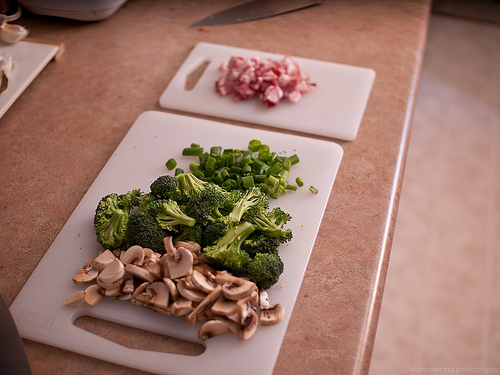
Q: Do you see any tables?
A: Yes, there is a table.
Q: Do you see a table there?
A: Yes, there is a table.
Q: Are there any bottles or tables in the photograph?
A: Yes, there is a table.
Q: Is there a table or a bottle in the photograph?
A: Yes, there is a table.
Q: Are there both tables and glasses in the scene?
A: No, there is a table but no glasses.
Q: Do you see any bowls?
A: No, there are no bowls.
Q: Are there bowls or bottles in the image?
A: No, there are no bowls or bottles.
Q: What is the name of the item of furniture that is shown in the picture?
A: The piece of furniture is a table.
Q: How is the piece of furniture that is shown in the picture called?
A: The piece of furniture is a table.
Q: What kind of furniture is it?
A: The piece of furniture is a table.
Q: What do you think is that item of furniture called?
A: This is a table.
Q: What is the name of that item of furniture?
A: This is a table.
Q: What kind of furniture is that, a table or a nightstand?
A: This is a table.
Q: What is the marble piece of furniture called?
A: The piece of furniture is a table.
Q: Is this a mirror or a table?
A: This is a table.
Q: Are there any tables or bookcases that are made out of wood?
A: No, there is a table but it is made of marble.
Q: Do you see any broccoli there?
A: Yes, there is broccoli.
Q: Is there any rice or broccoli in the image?
A: Yes, there is broccoli.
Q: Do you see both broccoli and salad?
A: No, there is broccoli but no salad.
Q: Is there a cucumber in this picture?
A: No, there are no cucumbers.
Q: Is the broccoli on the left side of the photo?
A: Yes, the broccoli is on the left of the image.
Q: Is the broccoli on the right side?
A: No, the broccoli is on the left of the image.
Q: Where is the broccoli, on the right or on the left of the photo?
A: The broccoli is on the left of the image.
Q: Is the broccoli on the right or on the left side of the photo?
A: The broccoli is on the left of the image.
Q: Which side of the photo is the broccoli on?
A: The broccoli is on the left of the image.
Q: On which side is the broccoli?
A: The broccoli is on the left of the image.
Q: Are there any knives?
A: Yes, there is a knife.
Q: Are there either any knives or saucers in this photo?
A: Yes, there is a knife.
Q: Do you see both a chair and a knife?
A: No, there is a knife but no chairs.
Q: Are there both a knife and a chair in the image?
A: No, there is a knife but no chairs.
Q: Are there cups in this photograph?
A: No, there are no cups.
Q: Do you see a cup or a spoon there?
A: No, there are no cups or spoons.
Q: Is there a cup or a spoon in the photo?
A: No, there are no cups or spoons.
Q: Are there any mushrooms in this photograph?
A: Yes, there are mushrooms.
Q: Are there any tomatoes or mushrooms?
A: Yes, there are mushrooms.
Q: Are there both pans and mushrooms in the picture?
A: No, there are mushrooms but no pans.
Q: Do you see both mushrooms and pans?
A: No, there are mushrooms but no pans.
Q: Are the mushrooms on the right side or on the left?
A: The mushrooms are on the left of the image.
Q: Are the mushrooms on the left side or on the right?
A: The mushrooms are on the left of the image.